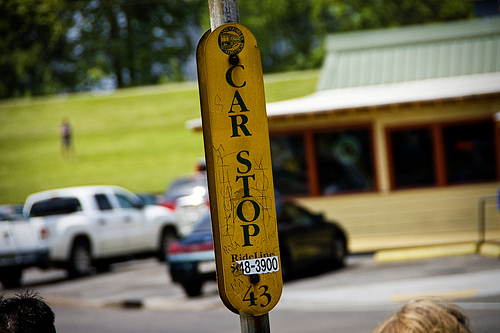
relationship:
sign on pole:
[193, 21, 296, 321] [224, 295, 302, 330]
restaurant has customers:
[228, 26, 494, 221] [268, 154, 352, 204]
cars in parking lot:
[7, 179, 362, 287] [79, 260, 495, 325]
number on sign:
[236, 277, 279, 314] [193, 21, 296, 321]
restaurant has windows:
[228, 26, 494, 221] [275, 133, 488, 187]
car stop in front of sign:
[213, 63, 267, 250] [193, 21, 296, 321]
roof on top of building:
[318, 22, 493, 67] [282, 37, 499, 240]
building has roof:
[282, 37, 499, 240] [318, 22, 493, 67]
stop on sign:
[225, 144, 263, 252] [193, 21, 296, 321]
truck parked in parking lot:
[16, 196, 176, 277] [79, 260, 495, 325]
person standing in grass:
[59, 103, 86, 172] [10, 133, 204, 184]